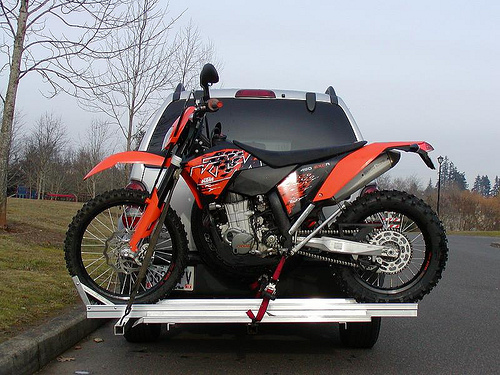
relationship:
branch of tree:
[131, 55, 169, 91] [80, 8, 190, 156]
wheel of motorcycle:
[58, 185, 201, 293] [47, 59, 442, 342]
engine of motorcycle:
[172, 173, 299, 270] [47, 59, 442, 342]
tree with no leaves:
[80, 8, 190, 156] [142, 28, 179, 57]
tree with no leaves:
[80, 8, 190, 156] [145, 24, 202, 78]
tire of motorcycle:
[58, 185, 201, 293] [47, 59, 442, 342]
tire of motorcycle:
[71, 173, 174, 244] [47, 59, 442, 342]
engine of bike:
[172, 173, 299, 270] [140, 161, 372, 287]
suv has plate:
[261, 73, 374, 143] [177, 261, 211, 294]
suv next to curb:
[261, 73, 374, 143] [38, 315, 76, 351]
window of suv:
[232, 98, 320, 150] [261, 73, 374, 143]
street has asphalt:
[448, 245, 481, 308] [461, 250, 487, 292]